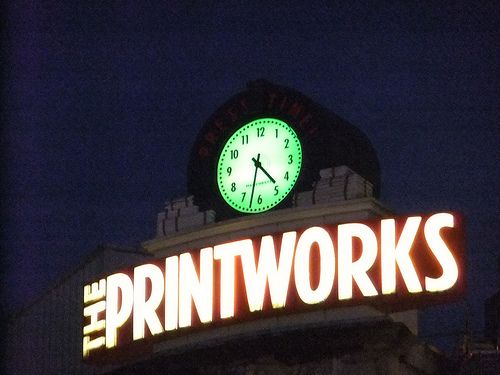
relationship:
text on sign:
[72, 214, 464, 332] [82, 211, 457, 357]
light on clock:
[211, 112, 300, 213] [214, 112, 305, 211]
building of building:
[0, 78, 500, 375] [2, 241, 153, 373]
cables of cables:
[43, 280, 70, 343] [0, 242, 154, 375]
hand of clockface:
[249, 153, 276, 207] [211, 113, 303, 212]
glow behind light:
[54, 206, 459, 319] [83, 118, 459, 357]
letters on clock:
[238, 168, 283, 190] [186, 113, 336, 220]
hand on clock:
[247, 167, 259, 204] [218, 112, 304, 217]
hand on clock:
[249, 153, 276, 207] [218, 112, 304, 217]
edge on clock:
[187, 74, 383, 211] [184, 73, 382, 225]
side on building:
[4, 243, 108, 371] [1, 77, 499, 371]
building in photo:
[1, 77, 499, 371] [6, 2, 498, 368]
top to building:
[135, 76, 395, 254] [3, 110, 495, 369]